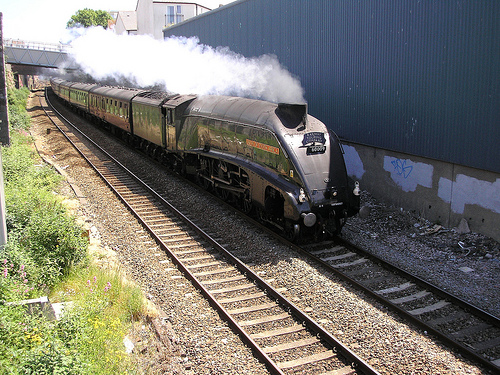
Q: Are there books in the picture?
A: No, there are no books.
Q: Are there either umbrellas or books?
A: No, there are no books or umbrellas.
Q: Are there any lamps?
A: No, there are no lamps.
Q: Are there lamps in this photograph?
A: No, there are no lamps.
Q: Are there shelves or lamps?
A: No, there are no lamps or shelves.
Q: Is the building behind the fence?
A: Yes, the building is behind the fence.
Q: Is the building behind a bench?
A: No, the building is behind the fence.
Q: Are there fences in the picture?
A: Yes, there is a fence.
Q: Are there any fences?
A: Yes, there is a fence.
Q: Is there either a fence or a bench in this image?
A: Yes, there is a fence.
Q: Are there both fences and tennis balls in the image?
A: No, there is a fence but no tennis balls.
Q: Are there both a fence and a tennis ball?
A: No, there is a fence but no tennis balls.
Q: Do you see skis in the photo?
A: No, there are no skis.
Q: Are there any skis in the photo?
A: No, there are no skis.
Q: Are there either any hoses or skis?
A: No, there are no skis or hoses.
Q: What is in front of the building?
A: The fence is in front of the building.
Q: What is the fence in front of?
A: The fence is in front of the building.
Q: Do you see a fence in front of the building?
A: Yes, there is a fence in front of the building.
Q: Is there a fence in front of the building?
A: Yes, there is a fence in front of the building.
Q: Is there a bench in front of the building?
A: No, there is a fence in front of the building.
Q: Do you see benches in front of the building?
A: No, there is a fence in front of the building.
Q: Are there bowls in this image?
A: No, there are no bowls.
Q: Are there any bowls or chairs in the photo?
A: No, there are no bowls or chairs.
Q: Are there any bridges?
A: Yes, there is a bridge.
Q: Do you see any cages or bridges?
A: Yes, there is a bridge.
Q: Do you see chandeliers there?
A: No, there are no chandeliers.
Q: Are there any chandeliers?
A: No, there are no chandeliers.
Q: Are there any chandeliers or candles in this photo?
A: No, there are no chandeliers or candles.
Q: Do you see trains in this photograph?
A: Yes, there is a train.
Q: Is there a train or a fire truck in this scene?
A: Yes, there is a train.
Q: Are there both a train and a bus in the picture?
A: No, there is a train but no buses.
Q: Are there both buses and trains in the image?
A: No, there is a train but no buses.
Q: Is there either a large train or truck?
A: Yes, there is a large train.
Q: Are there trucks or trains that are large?
A: Yes, the train is large.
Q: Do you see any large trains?
A: Yes, there is a large train.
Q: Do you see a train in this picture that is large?
A: Yes, there is a train that is large.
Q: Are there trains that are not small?
A: Yes, there is a large train.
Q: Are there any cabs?
A: No, there are no cabs.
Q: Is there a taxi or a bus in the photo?
A: No, there are no taxis or buses.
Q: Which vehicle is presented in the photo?
A: The vehicle is a train.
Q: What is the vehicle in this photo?
A: The vehicle is a train.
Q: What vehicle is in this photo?
A: The vehicle is a train.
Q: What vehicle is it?
A: The vehicle is a train.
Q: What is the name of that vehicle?
A: This is a train.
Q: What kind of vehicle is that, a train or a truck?
A: This is a train.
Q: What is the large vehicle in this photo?
A: The vehicle is a train.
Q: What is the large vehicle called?
A: The vehicle is a train.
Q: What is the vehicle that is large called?
A: The vehicle is a train.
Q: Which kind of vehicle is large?
A: The vehicle is a train.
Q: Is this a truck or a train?
A: This is a train.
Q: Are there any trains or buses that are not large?
A: No, there is a train but it is large.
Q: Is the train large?
A: Yes, the train is large.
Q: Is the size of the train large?
A: Yes, the train is large.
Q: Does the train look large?
A: Yes, the train is large.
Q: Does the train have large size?
A: Yes, the train is large.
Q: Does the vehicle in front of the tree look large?
A: Yes, the train is large.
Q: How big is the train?
A: The train is large.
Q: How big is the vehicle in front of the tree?
A: The train is large.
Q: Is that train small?
A: No, the train is large.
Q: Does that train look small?
A: No, the train is large.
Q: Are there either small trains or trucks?
A: No, there is a train but it is large.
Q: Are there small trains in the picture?
A: No, there is a train but it is large.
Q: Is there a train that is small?
A: No, there is a train but it is large.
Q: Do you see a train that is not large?
A: No, there is a train but it is large.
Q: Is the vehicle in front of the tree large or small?
A: The train is large.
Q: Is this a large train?
A: Yes, this is a large train.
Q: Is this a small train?
A: No, this is a large train.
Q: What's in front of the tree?
A: The train is in front of the tree.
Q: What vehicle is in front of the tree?
A: The vehicle is a train.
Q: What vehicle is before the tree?
A: The vehicle is a train.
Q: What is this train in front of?
A: The train is in front of the tree.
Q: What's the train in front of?
A: The train is in front of the tree.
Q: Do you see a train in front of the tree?
A: Yes, there is a train in front of the tree.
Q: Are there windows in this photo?
A: Yes, there are windows.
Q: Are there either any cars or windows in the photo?
A: Yes, there are windows.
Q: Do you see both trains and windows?
A: Yes, there are both windows and a train.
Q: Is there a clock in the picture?
A: No, there are no clocks.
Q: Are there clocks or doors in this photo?
A: No, there are no clocks or doors.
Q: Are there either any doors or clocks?
A: No, there are no clocks or doors.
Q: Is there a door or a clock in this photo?
A: No, there are no clocks or doors.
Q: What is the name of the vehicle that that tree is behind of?
A: The vehicle is a train.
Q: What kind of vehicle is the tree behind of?
A: The tree is behind the train.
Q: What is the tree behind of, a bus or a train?
A: The tree is behind a train.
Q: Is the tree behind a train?
A: Yes, the tree is behind a train.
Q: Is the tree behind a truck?
A: No, the tree is behind a train.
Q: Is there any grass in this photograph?
A: Yes, there is grass.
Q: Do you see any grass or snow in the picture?
A: Yes, there is grass.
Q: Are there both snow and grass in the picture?
A: No, there is grass but no snow.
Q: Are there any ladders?
A: No, there are no ladders.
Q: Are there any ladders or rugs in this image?
A: No, there are no ladders or rugs.